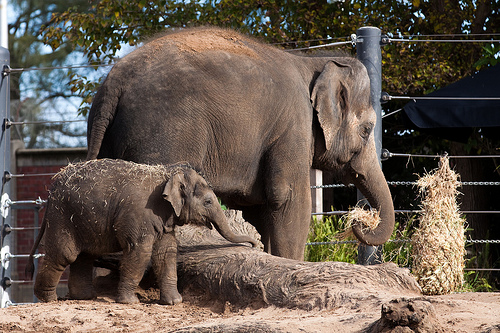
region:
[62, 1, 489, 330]
elephants walking outside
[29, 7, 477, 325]
two elephants walking outside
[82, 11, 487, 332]
a large elephant standing outside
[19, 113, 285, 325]
a small elephant standing outside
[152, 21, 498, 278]
a large elephant eatting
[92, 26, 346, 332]
elephants fenced in together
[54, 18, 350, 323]
two elephants fenced in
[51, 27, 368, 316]
elephants behind a fence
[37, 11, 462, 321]
elephants behind a metal fence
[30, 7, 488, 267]
elephants behind a tall fence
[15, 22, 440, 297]
elephants side by side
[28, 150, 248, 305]
smaller of the elephants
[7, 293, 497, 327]
dirt ground elephants stand on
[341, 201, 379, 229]
straw patch in elephant's trunk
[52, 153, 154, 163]
straw over elephant's back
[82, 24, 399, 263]
larger elephant on pair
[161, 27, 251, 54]
dirt patch on elephant back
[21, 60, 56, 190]
wire part of fence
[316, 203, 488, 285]
wild grass near fence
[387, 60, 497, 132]
covering over are near elephants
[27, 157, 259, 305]
baby elephant next to adult elephant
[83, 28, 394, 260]
adult elephant standing behind baby elephant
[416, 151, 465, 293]
wire basket filled with elephant's hay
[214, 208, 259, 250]
smaller trunk of baby elephant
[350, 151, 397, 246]
larger trunk of adult elephant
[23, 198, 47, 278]
smaller tail of baby elephant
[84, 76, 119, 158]
larger tail of adult elephant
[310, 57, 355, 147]
adult elephant's large right floppy ear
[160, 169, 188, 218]
baby elephant's small right floppy ear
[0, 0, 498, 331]
elephant enclosure surrounded by wire fencing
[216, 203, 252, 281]
What kind of a trunk does the elephant have?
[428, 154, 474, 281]
What kind of straw is this that is visible?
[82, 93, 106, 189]
What kind of tail does the elephant have?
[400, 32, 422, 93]
There are wires that are visible here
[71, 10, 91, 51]
There is a green tree that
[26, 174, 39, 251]
There is a brick building that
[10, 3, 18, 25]
The sky is a light blue color here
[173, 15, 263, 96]
The elephant has a very dirty back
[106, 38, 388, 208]
Jackson Mingus too this photo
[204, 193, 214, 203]
This elephant has a bright black eye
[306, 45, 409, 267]
the head of a baby elephant.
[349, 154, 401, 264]
a trunk on an elephant.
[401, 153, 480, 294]
a shreded tree trunk.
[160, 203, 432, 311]
a fallen tree trunk.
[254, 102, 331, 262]
a right front elephant leg.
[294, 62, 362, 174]
a right elephant ear.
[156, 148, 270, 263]
the head of an elephant.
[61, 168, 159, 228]
The body of an elephant.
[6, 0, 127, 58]
a leafy green branch.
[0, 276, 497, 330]
A field of dirt.